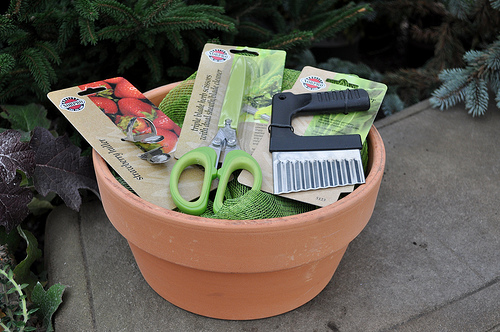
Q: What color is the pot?
A: Brown.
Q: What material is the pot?
A: Terracotta.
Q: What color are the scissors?
A: Green.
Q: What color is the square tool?
A: Black.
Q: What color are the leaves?
A: Green.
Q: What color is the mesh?
A: Green.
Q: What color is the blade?
A: Gray.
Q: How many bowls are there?
A: One.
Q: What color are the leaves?
A: Green and purple.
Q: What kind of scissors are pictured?
A: Herb shears.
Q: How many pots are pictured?
A: 1.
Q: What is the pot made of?
A: Clay.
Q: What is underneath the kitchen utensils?
A: Green mesh.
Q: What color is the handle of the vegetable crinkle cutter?
A: Black.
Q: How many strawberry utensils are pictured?
A: 1.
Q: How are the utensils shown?
A: Still packaged.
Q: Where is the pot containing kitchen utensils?
A: Garden.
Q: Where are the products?
A: In bowl.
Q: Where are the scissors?
A: In package.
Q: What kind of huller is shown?
A: Strawberry.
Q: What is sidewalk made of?
A: Cement.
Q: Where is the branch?
A: On sidewalk.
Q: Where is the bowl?
A: On surface.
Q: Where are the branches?
A: In background.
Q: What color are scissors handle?
A: Green.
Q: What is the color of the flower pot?
A: Brown.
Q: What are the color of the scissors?
A: Green.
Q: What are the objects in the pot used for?
A: Gardening.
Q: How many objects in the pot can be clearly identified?
A: 4.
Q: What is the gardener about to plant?
A: Strawberries.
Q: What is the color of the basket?
A: Green.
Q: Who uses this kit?
A: Gardeners.